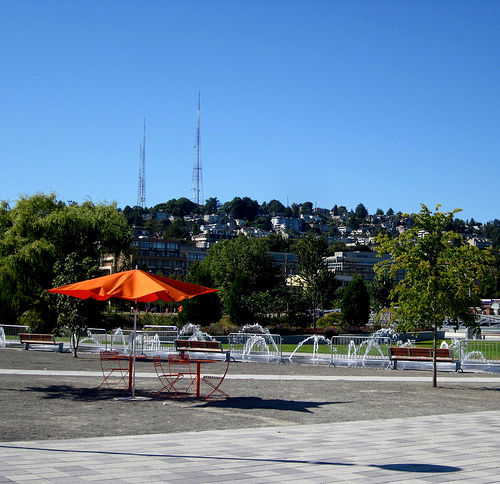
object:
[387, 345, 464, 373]
bench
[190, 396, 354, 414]
shadow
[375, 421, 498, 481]
ground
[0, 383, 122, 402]
shadows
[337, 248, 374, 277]
building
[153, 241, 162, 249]
window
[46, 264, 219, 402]
orange umbrella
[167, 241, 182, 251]
windows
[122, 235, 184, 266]
building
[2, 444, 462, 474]
shadow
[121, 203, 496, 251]
houses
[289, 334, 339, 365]
fountains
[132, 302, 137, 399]
pole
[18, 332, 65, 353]
wooden bench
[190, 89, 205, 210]
antenna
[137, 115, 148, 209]
antenna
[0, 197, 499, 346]
hill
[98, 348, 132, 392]
chair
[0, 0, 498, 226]
cloudless sky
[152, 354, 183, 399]
chair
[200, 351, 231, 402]
chair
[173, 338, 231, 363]
brown bench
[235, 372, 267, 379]
concrete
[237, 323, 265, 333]
water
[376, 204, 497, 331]
tree top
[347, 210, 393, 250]
houses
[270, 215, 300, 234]
buildings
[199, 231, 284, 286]
tree tops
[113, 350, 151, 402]
stand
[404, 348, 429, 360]
back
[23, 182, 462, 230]
horizon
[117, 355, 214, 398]
table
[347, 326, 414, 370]
fountain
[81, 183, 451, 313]
hilltop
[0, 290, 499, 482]
park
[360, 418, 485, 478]
cement